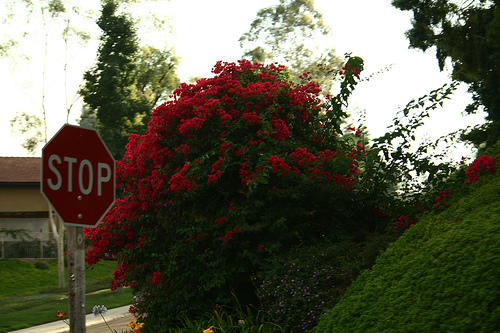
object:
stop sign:
[41, 124, 117, 227]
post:
[64, 221, 87, 332]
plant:
[83, 57, 363, 314]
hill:
[312, 183, 499, 333]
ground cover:
[320, 183, 499, 331]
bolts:
[77, 193, 82, 222]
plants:
[83, 0, 499, 333]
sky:
[1, 0, 493, 199]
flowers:
[127, 319, 219, 332]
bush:
[83, 54, 365, 333]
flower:
[91, 305, 107, 316]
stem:
[102, 315, 113, 332]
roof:
[1, 158, 61, 213]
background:
[2, 0, 172, 331]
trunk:
[46, 202, 67, 286]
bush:
[464, 155, 495, 186]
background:
[298, 3, 498, 218]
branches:
[1, 4, 94, 155]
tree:
[1, 0, 98, 156]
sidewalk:
[2, 301, 141, 332]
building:
[1, 156, 57, 257]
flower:
[57, 310, 66, 320]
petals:
[56, 310, 65, 319]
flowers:
[176, 115, 208, 137]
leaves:
[132, 112, 382, 308]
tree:
[48, 203, 67, 288]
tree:
[392, 1, 499, 152]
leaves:
[392, 0, 499, 149]